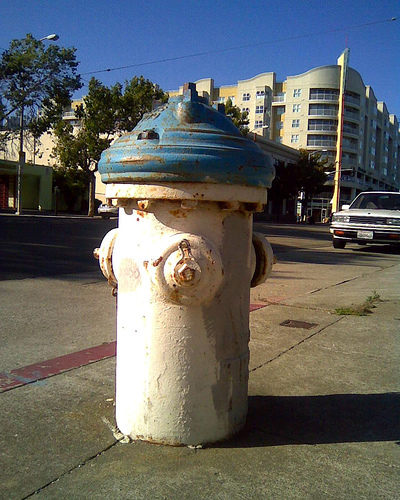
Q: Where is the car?
A: In the street.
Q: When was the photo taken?
A: Day time.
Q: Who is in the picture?
A: No one.